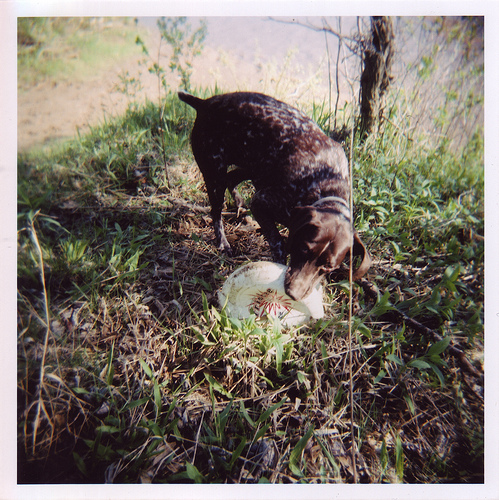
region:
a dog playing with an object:
[154, 63, 383, 358]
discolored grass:
[25, 138, 228, 460]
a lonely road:
[18, 21, 191, 139]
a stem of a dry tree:
[346, 13, 413, 154]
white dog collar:
[305, 182, 360, 221]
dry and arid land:
[20, 43, 163, 445]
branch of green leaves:
[110, 378, 388, 485]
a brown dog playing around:
[176, 87, 374, 285]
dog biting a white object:
[178, 92, 389, 327]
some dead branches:
[35, 291, 84, 447]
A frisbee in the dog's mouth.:
[90, 79, 389, 372]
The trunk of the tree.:
[335, 14, 393, 139]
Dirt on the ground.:
[29, 82, 88, 109]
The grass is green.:
[99, 105, 145, 131]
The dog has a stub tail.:
[167, 82, 206, 104]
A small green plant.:
[138, 11, 200, 75]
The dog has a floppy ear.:
[341, 231, 373, 290]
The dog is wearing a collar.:
[305, 172, 352, 213]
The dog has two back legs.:
[199, 157, 256, 254]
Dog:
[140, 64, 395, 317]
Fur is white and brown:
[161, 83, 393, 309]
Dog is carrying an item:
[192, 217, 360, 356]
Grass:
[71, 188, 453, 483]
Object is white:
[205, 240, 343, 378]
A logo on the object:
[242, 274, 303, 327]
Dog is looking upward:
[286, 206, 349, 291]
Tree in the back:
[324, 21, 417, 164]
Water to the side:
[253, 24, 473, 142]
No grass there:
[27, 49, 112, 139]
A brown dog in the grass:
[193, 88, 379, 276]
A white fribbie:
[202, 268, 333, 342]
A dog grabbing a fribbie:
[189, 93, 409, 343]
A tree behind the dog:
[345, 3, 411, 142]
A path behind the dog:
[59, 43, 224, 124]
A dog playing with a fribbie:
[171, 67, 374, 365]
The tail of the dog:
[157, 77, 204, 134]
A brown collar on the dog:
[311, 193, 364, 211]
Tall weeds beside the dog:
[361, 71, 482, 211]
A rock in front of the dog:
[198, 431, 343, 478]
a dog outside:
[128, 44, 454, 361]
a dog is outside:
[124, 43, 391, 370]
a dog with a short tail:
[114, 47, 384, 337]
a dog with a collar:
[167, 52, 400, 310]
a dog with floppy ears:
[153, 56, 415, 334]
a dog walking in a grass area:
[126, 55, 436, 412]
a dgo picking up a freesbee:
[138, 60, 409, 395]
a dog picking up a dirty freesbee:
[116, 57, 394, 389]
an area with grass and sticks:
[51, 67, 492, 463]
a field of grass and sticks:
[47, 81, 486, 434]